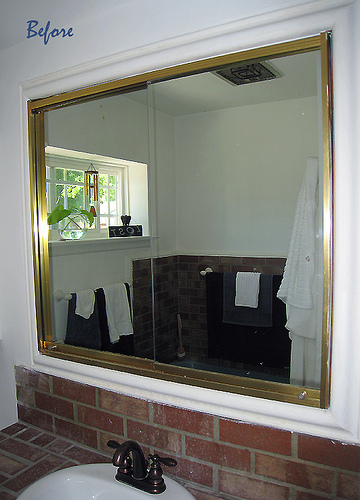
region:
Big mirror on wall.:
[15, 29, 347, 417]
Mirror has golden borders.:
[21, 27, 339, 412]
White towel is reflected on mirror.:
[228, 263, 266, 311]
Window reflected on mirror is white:
[47, 144, 154, 245]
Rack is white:
[55, 274, 138, 343]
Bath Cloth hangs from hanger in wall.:
[271, 148, 335, 392]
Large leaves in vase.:
[47, 197, 101, 243]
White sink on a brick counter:
[12, 431, 216, 497]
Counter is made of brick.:
[2, 419, 92, 496]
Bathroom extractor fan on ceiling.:
[206, 59, 287, 100]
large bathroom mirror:
[13, 78, 336, 416]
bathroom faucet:
[96, 432, 182, 493]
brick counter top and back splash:
[13, 368, 330, 488]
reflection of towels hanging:
[196, 261, 288, 355]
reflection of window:
[50, 152, 150, 249]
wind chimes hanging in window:
[76, 155, 108, 219]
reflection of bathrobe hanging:
[276, 151, 332, 394]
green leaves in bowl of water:
[48, 203, 98, 248]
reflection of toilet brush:
[164, 311, 194, 364]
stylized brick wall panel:
[115, 254, 289, 361]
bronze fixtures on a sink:
[109, 432, 171, 494]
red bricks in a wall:
[188, 433, 267, 476]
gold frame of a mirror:
[322, 311, 328, 353]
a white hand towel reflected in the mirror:
[233, 267, 265, 312]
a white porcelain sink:
[74, 469, 107, 490]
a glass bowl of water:
[58, 228, 85, 236]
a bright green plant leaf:
[51, 206, 71, 221]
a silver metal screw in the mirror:
[295, 386, 311, 403]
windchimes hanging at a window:
[78, 158, 115, 200]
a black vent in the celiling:
[218, 58, 285, 84]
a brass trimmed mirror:
[9, 19, 341, 372]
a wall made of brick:
[14, 359, 233, 497]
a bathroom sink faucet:
[72, 442, 195, 489]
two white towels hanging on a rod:
[48, 267, 141, 347]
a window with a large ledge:
[23, 151, 157, 267]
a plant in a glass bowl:
[31, 193, 104, 241]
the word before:
[0, 19, 88, 48]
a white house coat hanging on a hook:
[267, 152, 322, 381]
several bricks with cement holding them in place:
[0, 401, 98, 466]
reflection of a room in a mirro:
[0, 11, 336, 414]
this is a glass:
[44, 107, 293, 313]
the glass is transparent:
[129, 191, 267, 340]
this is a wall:
[22, 377, 84, 425]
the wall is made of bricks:
[23, 393, 103, 435]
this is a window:
[54, 167, 142, 237]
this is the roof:
[180, 83, 218, 105]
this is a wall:
[206, 136, 282, 222]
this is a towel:
[107, 286, 129, 327]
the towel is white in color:
[109, 293, 120, 316]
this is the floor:
[4, 433, 33, 474]